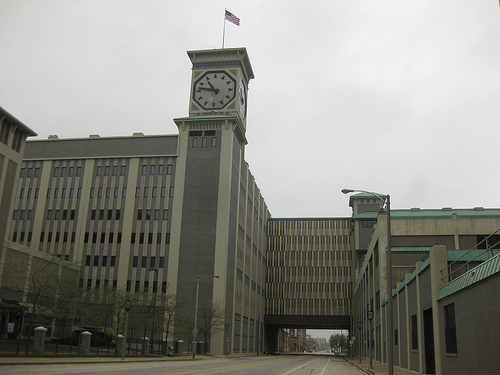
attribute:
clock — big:
[188, 49, 248, 131]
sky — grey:
[2, 1, 500, 219]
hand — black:
[197, 86, 220, 93]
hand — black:
[207, 81, 218, 94]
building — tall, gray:
[25, 139, 269, 357]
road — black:
[4, 351, 361, 374]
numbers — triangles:
[198, 73, 233, 110]